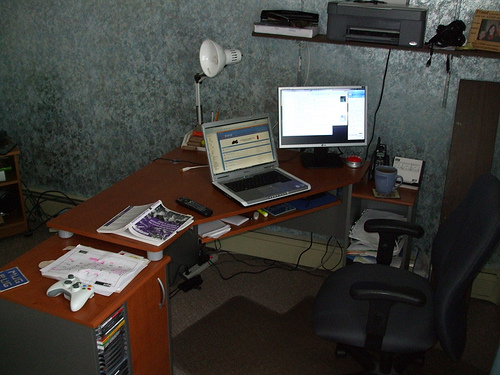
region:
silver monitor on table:
[256, 64, 391, 178]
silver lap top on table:
[182, 105, 328, 214]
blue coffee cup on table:
[360, 148, 419, 214]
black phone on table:
[363, 117, 404, 192]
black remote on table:
[150, 166, 255, 246]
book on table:
[87, 180, 195, 270]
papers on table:
[23, 223, 160, 310]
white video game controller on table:
[44, 255, 101, 320]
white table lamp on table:
[174, 16, 272, 174]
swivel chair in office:
[300, 150, 499, 363]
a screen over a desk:
[268, 79, 375, 156]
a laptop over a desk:
[194, 105, 312, 211]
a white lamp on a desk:
[177, 28, 247, 155]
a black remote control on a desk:
[170, 189, 220, 221]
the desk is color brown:
[9, 120, 430, 372]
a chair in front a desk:
[170, 138, 499, 370]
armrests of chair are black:
[347, 208, 435, 350]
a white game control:
[39, 265, 105, 320]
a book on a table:
[93, 190, 198, 256]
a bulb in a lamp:
[192, 32, 247, 84]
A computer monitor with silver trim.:
[278, 85, 368, 170]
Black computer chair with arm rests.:
[318, 176, 499, 373]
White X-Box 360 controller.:
[46, 273, 96, 311]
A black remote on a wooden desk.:
[176, 195, 213, 215]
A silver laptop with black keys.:
[201, 113, 311, 208]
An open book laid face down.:
[98, 200, 195, 245]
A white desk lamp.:
[189, 35, 242, 137]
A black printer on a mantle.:
[328, 0, 428, 49]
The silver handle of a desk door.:
[157, 273, 166, 308]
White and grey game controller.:
[46, 272, 97, 311]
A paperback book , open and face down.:
[96, 198, 193, 245]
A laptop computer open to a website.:
[200, 110, 313, 207]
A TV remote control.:
[173, 193, 215, 217]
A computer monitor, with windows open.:
[276, 85, 368, 171]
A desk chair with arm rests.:
[311, 171, 498, 373]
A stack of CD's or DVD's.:
[93, 301, 133, 373]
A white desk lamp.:
[188, 33, 245, 126]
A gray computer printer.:
[326, 0, 431, 52]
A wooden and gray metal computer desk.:
[1, 36, 426, 371]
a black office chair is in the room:
[311, 168, 491, 369]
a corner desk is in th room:
[61, 125, 365, 346]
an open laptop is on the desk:
[200, 116, 311, 207]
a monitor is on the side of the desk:
[275, 77, 371, 169]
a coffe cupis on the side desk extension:
[348, 155, 425, 250]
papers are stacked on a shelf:
[344, 176, 419, 277]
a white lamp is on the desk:
[178, 29, 244, 167]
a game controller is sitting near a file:
[43, 268, 99, 313]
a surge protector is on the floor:
[176, 248, 224, 290]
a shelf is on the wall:
[242, 4, 497, 70]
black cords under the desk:
[229, 253, 251, 278]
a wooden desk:
[151, 168, 196, 190]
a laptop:
[209, 123, 297, 204]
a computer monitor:
[278, 89, 370, 141]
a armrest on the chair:
[351, 278, 416, 303]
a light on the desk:
[196, 33, 245, 77]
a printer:
[329, 8, 402, 40]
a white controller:
[48, 275, 100, 312]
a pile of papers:
[351, 220, 366, 257]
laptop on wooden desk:
[202, 113, 309, 205]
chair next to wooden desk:
[313, 170, 498, 374]